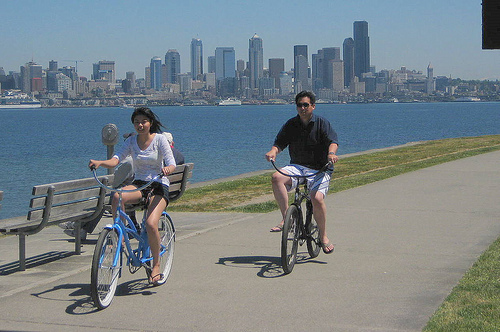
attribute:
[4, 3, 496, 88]
sky — blue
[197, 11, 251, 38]
clouds — white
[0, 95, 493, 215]
water — blue, rippled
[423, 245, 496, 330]
lawn — green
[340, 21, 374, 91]
building — tall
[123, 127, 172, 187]
top — white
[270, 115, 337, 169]
top — black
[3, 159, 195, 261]
bench — metal, wooden, long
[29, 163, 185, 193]
plank — wooden, long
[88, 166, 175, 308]
bicycle — blue, cornflower blue, old fashioned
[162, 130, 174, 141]
hair — grey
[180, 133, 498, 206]
grass — green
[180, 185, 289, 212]
spots — bare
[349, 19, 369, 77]
office building — flat topped, tall, black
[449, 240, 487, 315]
patch — small, lush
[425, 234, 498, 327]
grass — green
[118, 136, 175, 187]
shirt — white, long sleeved, scoop necked